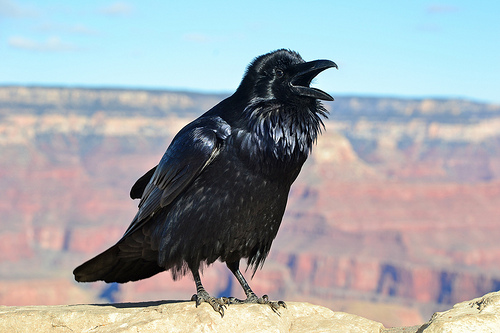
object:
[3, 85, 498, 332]
mountain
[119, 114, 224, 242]
wing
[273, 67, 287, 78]
eye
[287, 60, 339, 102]
beak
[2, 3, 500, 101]
sky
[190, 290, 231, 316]
foog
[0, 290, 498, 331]
rock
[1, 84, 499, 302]
rocks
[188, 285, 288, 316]
feet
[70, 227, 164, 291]
tail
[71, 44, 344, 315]
bird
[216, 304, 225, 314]
nail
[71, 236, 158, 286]
tail feathers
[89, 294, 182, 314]
shadow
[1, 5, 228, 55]
cloud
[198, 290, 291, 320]
claws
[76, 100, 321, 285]
feathers